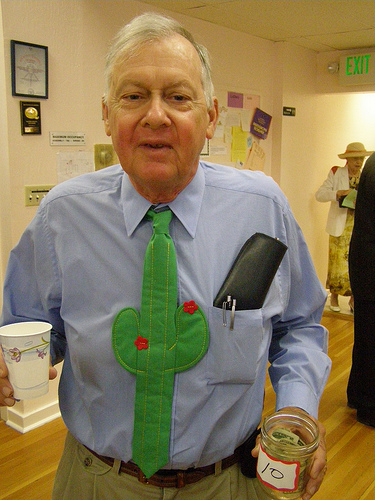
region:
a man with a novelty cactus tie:
[110, 208, 209, 478]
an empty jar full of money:
[251, 406, 319, 498]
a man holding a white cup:
[0, 321, 52, 397]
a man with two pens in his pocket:
[219, 293, 238, 331]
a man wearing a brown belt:
[65, 423, 273, 491]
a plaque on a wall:
[18, 99, 44, 137]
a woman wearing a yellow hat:
[334, 143, 373, 160]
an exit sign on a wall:
[339, 53, 374, 87]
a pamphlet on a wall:
[249, 107, 272, 143]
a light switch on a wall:
[20, 182, 70, 208]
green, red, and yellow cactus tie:
[110, 206, 213, 481]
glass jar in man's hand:
[246, 408, 322, 497]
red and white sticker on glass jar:
[251, 440, 302, 493]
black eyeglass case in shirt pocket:
[212, 230, 291, 316]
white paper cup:
[0, 318, 57, 403]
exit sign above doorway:
[326, 48, 374, 87]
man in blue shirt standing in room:
[1, 6, 336, 498]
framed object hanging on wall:
[7, 34, 53, 100]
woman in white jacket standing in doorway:
[316, 139, 373, 315]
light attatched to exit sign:
[322, 58, 341, 78]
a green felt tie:
[107, 210, 221, 484]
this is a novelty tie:
[108, 212, 214, 484]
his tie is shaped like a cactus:
[99, 204, 207, 483]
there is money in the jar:
[252, 401, 327, 497]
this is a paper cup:
[0, 311, 68, 414]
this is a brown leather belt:
[60, 425, 267, 492]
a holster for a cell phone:
[228, 428, 269, 480]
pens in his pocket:
[211, 292, 244, 343]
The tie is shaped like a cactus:
[95, 200, 205, 487]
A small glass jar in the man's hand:
[256, 401, 321, 496]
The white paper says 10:
[251, 457, 299, 488]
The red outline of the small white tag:
[289, 461, 301, 489]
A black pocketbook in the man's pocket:
[213, 226, 288, 312]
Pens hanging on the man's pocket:
[221, 295, 241, 326]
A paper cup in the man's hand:
[0, 316, 61, 402]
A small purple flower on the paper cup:
[8, 346, 48, 360]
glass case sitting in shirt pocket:
[222, 232, 302, 333]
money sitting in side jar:
[261, 408, 313, 478]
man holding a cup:
[10, 314, 81, 422]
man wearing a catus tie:
[116, 288, 199, 498]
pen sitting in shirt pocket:
[203, 301, 263, 340]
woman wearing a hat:
[308, 132, 371, 179]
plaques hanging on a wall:
[7, 39, 62, 165]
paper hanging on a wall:
[223, 105, 278, 169]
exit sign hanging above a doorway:
[306, 44, 365, 79]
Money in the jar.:
[257, 409, 315, 489]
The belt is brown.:
[93, 448, 237, 491]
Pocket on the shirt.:
[201, 299, 265, 391]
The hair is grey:
[99, 19, 177, 44]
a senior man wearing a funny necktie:
[0, 12, 328, 498]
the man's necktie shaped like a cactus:
[110, 208, 209, 480]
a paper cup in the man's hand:
[0, 320, 53, 399]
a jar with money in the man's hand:
[256, 411, 318, 499]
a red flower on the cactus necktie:
[133, 335, 148, 351]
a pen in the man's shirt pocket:
[228, 298, 237, 331]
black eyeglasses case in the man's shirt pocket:
[212, 231, 287, 309]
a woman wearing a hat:
[314, 142, 373, 311]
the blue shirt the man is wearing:
[0, 161, 331, 470]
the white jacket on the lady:
[315, 164, 350, 237]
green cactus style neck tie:
[114, 209, 210, 477]